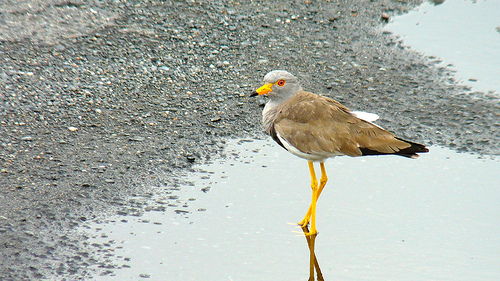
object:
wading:
[291, 160, 331, 245]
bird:
[248, 68, 430, 238]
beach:
[0, 0, 500, 278]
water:
[56, 130, 500, 281]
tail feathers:
[361, 131, 434, 161]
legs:
[308, 157, 319, 232]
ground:
[0, 0, 500, 279]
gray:
[280, 90, 288, 98]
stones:
[184, 160, 208, 176]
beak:
[247, 80, 270, 100]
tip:
[246, 91, 258, 101]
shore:
[0, 0, 500, 281]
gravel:
[0, 0, 500, 281]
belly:
[277, 133, 333, 162]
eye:
[276, 77, 290, 88]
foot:
[290, 228, 321, 240]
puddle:
[69, 135, 500, 281]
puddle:
[374, 0, 500, 99]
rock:
[184, 151, 201, 168]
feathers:
[341, 131, 375, 146]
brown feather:
[290, 102, 326, 125]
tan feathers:
[315, 138, 331, 155]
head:
[250, 68, 306, 99]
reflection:
[299, 233, 325, 281]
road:
[0, 0, 500, 281]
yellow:
[311, 176, 320, 219]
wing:
[281, 108, 375, 159]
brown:
[337, 123, 356, 130]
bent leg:
[307, 163, 329, 224]